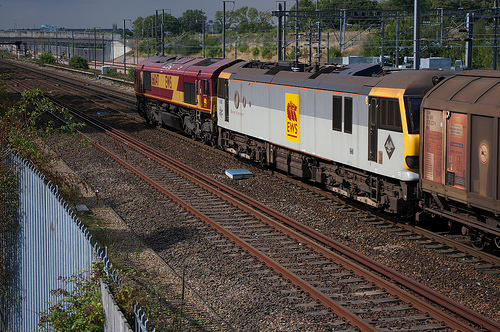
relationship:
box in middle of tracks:
[225, 167, 253, 181] [1, 59, 500, 331]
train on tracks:
[135, 54, 500, 254] [1, 59, 500, 331]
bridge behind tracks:
[1, 28, 135, 68] [1, 59, 500, 331]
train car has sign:
[217, 59, 457, 221] [284, 93, 300, 144]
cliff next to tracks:
[118, 25, 500, 73] [1, 59, 500, 331]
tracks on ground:
[1, 59, 500, 331] [0, 49, 500, 331]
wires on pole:
[112, 11, 500, 63] [414, 1, 420, 71]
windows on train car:
[332, 96, 353, 135] [217, 59, 457, 221]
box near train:
[225, 167, 253, 181] [135, 54, 500, 254]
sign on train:
[284, 93, 300, 144] [135, 54, 500, 254]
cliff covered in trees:
[118, 25, 500, 73] [133, 1, 500, 72]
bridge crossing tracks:
[1, 28, 135, 68] [1, 59, 500, 331]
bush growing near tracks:
[68, 56, 89, 70] [1, 59, 500, 331]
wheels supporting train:
[145, 116, 489, 250] [135, 54, 500, 254]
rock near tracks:
[282, 198, 287, 202] [1, 59, 500, 331]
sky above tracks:
[1, 0, 317, 34] [1, 59, 500, 331]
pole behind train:
[414, 1, 420, 71] [135, 54, 500, 254]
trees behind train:
[133, 1, 500, 72] [135, 54, 500, 254]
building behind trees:
[206, 20, 220, 35] [133, 1, 500, 72]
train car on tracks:
[217, 59, 457, 221] [1, 59, 500, 331]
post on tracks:
[93, 27, 97, 68] [1, 59, 500, 331]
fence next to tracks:
[2, 150, 157, 331] [1, 59, 500, 331]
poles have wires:
[71, 1, 500, 75] [112, 11, 500, 63]